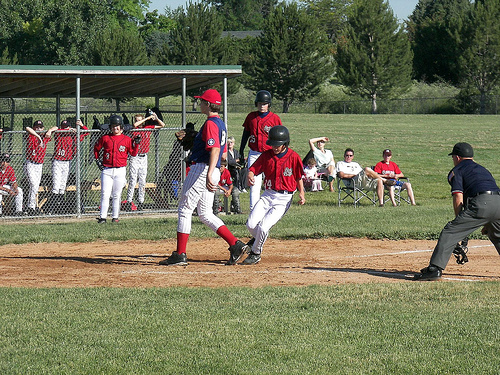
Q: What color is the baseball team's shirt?
A: Red.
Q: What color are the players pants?
A: White.